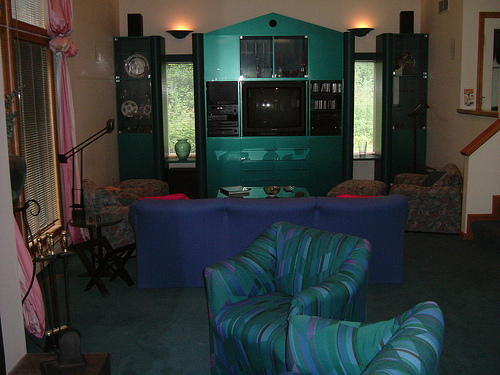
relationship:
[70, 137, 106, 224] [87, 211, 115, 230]
mic stand on table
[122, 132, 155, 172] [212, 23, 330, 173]
cabinet next to entertainment center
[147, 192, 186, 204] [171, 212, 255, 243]
pillow on couch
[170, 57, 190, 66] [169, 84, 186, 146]
trim on window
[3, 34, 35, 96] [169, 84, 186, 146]
blinds of window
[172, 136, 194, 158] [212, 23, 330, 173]
vase inside entertainment center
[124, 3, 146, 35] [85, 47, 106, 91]
speaker on wall